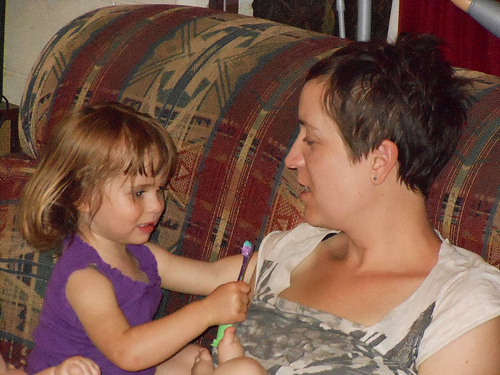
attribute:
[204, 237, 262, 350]
toothbrush — purple, green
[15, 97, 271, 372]
girl — little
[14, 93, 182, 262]
hair — blond, blonde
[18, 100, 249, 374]
girl — young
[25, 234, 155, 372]
shirt — purple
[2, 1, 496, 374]
couch — beige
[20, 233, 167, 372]
shirt — purple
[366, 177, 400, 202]
earring — small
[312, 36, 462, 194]
hair — short, thin, dark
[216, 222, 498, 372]
shirt — white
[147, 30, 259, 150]
sofa — large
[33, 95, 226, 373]
girl — young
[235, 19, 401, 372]
woman — head of